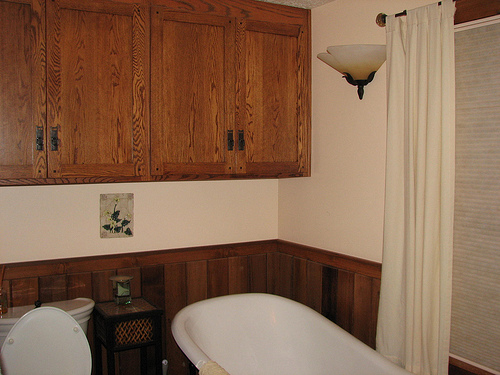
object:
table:
[91, 298, 165, 374]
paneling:
[37, 272, 69, 303]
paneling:
[137, 257, 164, 314]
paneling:
[162, 255, 187, 316]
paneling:
[182, 250, 213, 302]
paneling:
[206, 254, 261, 297]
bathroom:
[0, 0, 499, 375]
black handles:
[226, 130, 246, 151]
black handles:
[35, 125, 58, 152]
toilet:
[0, 298, 95, 362]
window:
[387, 0, 500, 374]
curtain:
[379, 8, 450, 374]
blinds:
[376, 0, 461, 375]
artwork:
[99, 192, 135, 238]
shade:
[449, 15, 499, 375]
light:
[315, 43, 385, 100]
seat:
[2, 306, 97, 375]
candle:
[109, 275, 135, 305]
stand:
[90, 293, 165, 374]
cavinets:
[1, 7, 309, 178]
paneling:
[350, 274, 380, 350]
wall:
[2, 173, 280, 341]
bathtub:
[171, 292, 411, 374]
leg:
[93, 345, 103, 370]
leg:
[146, 342, 163, 372]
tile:
[95, 191, 135, 238]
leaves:
[114, 215, 133, 236]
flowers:
[102, 196, 133, 235]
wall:
[277, 0, 453, 266]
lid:
[0, 303, 96, 375]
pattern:
[114, 318, 158, 344]